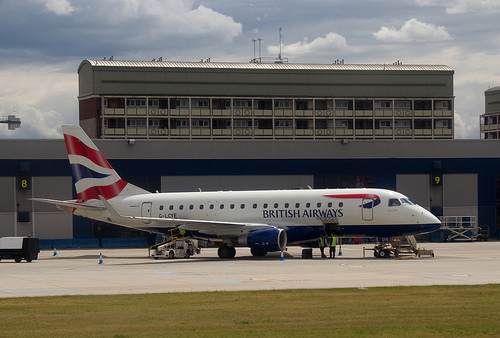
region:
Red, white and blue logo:
[22, 97, 222, 269]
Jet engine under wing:
[195, 195, 330, 277]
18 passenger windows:
[155, 194, 361, 226]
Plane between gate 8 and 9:
[7, 73, 496, 281]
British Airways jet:
[21, 72, 488, 280]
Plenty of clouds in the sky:
[3, 1, 499, 135]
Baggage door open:
[111, 199, 247, 276]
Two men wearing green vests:
[294, 199, 374, 274]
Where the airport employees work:
[73, 33, 473, 146]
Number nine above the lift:
[403, 141, 496, 264]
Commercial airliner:
[10, 113, 468, 270]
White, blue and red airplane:
[0, 130, 455, 285]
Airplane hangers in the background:
[5, 127, 495, 247]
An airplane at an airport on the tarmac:
[0, 10, 499, 325]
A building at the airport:
[70, 45, 450, 180]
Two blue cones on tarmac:
[45, 240, 110, 270]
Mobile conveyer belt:
[136, 220, 206, 261]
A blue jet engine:
[230, 215, 290, 245]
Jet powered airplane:
[7, 110, 462, 272]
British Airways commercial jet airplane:
[15, 106, 457, 273]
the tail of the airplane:
[48, 116, 143, 211]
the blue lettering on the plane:
[262, 206, 344, 219]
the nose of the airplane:
[415, 193, 449, 248]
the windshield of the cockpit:
[387, 196, 417, 208]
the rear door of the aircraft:
[132, 197, 160, 227]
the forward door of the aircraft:
[354, 190, 381, 224]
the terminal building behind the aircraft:
[2, 75, 498, 249]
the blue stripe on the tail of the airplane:
[72, 160, 108, 181]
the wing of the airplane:
[123, 206, 283, 253]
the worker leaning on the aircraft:
[315, 231, 330, 260]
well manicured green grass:
[56, 304, 253, 328]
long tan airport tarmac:
[43, 267, 252, 285]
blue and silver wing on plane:
[237, 210, 300, 265]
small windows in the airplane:
[152, 193, 262, 215]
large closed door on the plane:
[348, 191, 383, 234]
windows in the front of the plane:
[381, 182, 439, 216]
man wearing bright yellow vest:
[318, 225, 353, 247]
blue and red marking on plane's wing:
[38, 107, 139, 234]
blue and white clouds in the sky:
[55, 10, 210, 43]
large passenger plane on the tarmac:
[53, 116, 443, 276]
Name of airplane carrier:
[262, 207, 336, 217]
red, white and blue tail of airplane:
[64, 125, 118, 200]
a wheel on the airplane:
[218, 243, 238, 264]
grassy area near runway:
[94, 304, 271, 336]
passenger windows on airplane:
[184, 197, 272, 212]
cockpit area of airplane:
[382, 189, 424, 216]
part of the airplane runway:
[30, 261, 235, 293]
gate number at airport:
[426, 170, 456, 197]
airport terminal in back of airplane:
[81, 57, 457, 139]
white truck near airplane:
[153, 239, 198, 259]